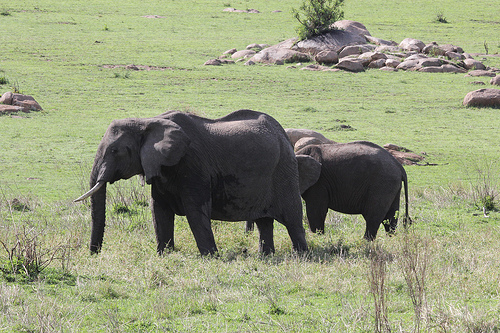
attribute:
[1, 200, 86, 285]
tufts — grassy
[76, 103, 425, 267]
elephants — standing, together, walking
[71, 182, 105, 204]
tusk — white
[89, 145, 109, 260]
trunk — long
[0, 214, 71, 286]
bush — small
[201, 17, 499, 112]
rocks — in row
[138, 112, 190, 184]
ears — large, grey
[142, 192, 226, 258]
legs — grey, large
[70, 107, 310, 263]
elephant — in front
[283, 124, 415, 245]
elephant — in back, small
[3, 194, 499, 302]
grass — green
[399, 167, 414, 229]
tail — grey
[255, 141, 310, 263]
legs — grey